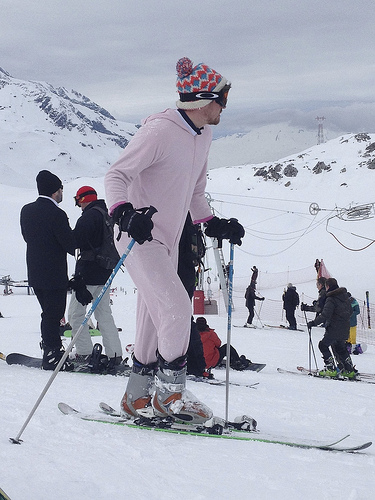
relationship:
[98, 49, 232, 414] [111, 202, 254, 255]
man wearing gloves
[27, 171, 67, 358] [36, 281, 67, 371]
man wearing pants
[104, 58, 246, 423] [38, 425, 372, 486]
man are standing on snow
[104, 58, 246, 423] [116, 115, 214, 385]
man wearing outfit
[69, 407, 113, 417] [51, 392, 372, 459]
snow on top of skis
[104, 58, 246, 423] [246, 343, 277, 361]
man seated on top of snow